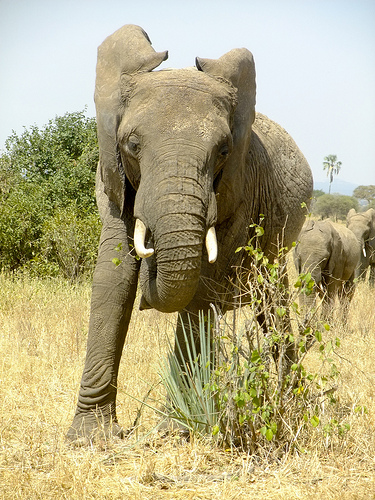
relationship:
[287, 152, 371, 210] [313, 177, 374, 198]
mountain on horizon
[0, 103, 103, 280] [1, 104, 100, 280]
leaves on bush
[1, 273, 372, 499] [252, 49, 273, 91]
grass on ground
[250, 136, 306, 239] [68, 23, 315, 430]
wrinkles on skin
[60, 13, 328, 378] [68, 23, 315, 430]
elephant has skin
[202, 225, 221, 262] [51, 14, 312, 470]
tusk on elephant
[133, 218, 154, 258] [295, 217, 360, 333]
tusk on elephant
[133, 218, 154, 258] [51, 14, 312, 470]
tusk on elephant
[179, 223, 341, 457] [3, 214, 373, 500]
grass in field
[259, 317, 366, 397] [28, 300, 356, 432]
grass in field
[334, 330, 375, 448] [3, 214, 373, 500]
grass in field